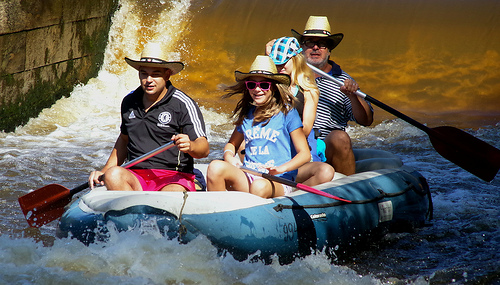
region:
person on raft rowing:
[143, 64, 201, 189]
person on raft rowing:
[234, 59, 292, 174]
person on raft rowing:
[294, 30, 365, 127]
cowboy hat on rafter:
[134, 41, 219, 88]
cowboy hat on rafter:
[222, 34, 284, 107]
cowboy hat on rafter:
[287, 4, 358, 49]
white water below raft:
[82, 200, 364, 275]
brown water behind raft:
[377, 24, 497, 86]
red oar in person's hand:
[23, 150, 135, 258]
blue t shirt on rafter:
[232, 104, 312, 181]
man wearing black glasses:
[298, 35, 332, 51]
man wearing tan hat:
[289, 9, 349, 40]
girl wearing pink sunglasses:
[242, 77, 274, 91]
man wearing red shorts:
[120, 160, 196, 190]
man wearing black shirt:
[117, 63, 202, 165]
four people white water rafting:
[11, 10, 465, 273]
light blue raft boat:
[56, 185, 435, 252]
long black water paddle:
[402, 89, 499, 179]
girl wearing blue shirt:
[231, 77, 300, 172]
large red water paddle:
[13, 178, 80, 230]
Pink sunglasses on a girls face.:
[242, 78, 274, 90]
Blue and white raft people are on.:
[55, 159, 433, 261]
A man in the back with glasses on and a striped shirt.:
[291, 14, 372, 174]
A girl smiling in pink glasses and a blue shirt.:
[205, 54, 311, 193]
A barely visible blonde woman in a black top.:
[263, 35, 317, 159]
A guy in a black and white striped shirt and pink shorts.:
[88, 41, 207, 192]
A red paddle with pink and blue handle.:
[17, 136, 181, 227]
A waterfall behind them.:
[116, 1, 498, 124]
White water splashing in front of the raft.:
[1, 224, 371, 284]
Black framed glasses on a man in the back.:
[299, 37, 331, 49]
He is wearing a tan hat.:
[132, 35, 199, 74]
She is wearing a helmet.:
[256, 28, 303, 66]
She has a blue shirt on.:
[221, 103, 303, 168]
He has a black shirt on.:
[107, 93, 206, 167]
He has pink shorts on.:
[118, 153, 186, 192]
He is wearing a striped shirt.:
[308, 71, 363, 141]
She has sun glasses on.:
[236, 78, 277, 91]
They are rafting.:
[8, 9, 499, 270]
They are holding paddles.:
[28, 13, 493, 280]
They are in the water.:
[3, 10, 495, 282]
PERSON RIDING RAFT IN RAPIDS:
[119, 43, 174, 207]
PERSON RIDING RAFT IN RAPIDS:
[222, 43, 300, 205]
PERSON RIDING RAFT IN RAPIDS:
[301, 18, 379, 189]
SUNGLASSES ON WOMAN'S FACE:
[238, 79, 280, 101]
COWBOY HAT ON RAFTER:
[104, 37, 189, 101]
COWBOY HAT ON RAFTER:
[240, 48, 273, 82]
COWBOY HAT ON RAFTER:
[315, 25, 329, 35]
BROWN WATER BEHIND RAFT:
[419, 37, 481, 119]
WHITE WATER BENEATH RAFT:
[84, 243, 175, 283]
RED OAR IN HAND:
[8, 168, 83, 221]